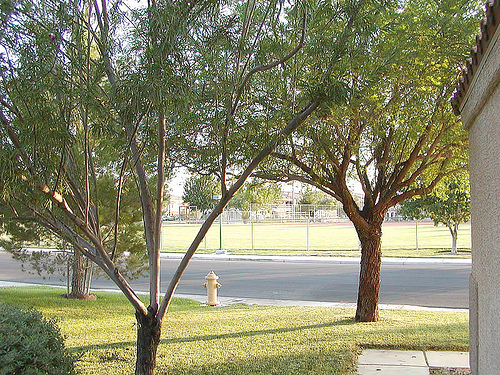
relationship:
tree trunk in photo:
[134, 312, 166, 372] [3, 2, 480, 372]